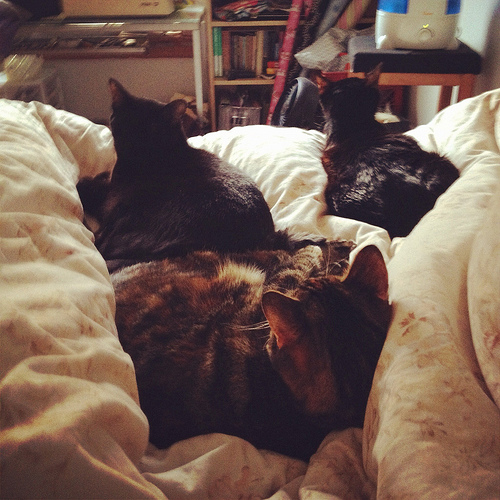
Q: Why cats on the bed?
A: To rest.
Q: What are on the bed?
A: Cats.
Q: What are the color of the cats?
A: Black and brown.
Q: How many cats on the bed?
A: Three.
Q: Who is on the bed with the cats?
A: No one.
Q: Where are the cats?
A: On the bed.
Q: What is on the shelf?
A: Books.